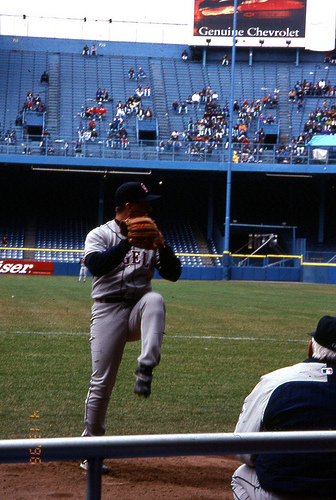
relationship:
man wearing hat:
[84, 179, 166, 437] [115, 179, 154, 202]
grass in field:
[197, 342, 222, 372] [192, 273, 297, 368]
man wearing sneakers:
[81, 179, 181, 470] [138, 364, 154, 397]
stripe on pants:
[83, 384, 90, 408] [80, 298, 164, 431]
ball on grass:
[5, 293, 20, 303] [247, 289, 266, 320]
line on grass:
[186, 331, 220, 341] [223, 350, 244, 379]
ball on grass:
[11, 295, 14, 299] [213, 349, 234, 374]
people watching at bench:
[173, 92, 262, 134] [158, 81, 196, 93]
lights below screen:
[193, 35, 295, 52] [191, 0, 305, 34]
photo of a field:
[14, 71, 291, 446] [182, 274, 265, 361]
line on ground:
[212, 329, 232, 344] [191, 377, 199, 383]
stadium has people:
[24, 100, 271, 215] [84, 114, 233, 117]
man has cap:
[230, 312, 336, 500] [319, 321, 322, 336]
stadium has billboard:
[37, 195, 292, 212] [202, 34, 230, 36]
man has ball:
[230, 312, 336, 500] [139, 226, 146, 234]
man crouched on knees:
[284, 367, 293, 385] [236, 461, 240, 500]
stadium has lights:
[40, 207, 321, 217] [195, 40, 301, 41]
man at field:
[230, 312, 336, 500] [36, 285, 48, 328]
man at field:
[230, 312, 336, 500] [197, 296, 239, 357]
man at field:
[230, 312, 336, 500] [22, 290, 28, 331]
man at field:
[230, 312, 336, 500] [26, 327, 40, 422]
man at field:
[230, 312, 336, 500] [22, 268, 32, 333]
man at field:
[230, 312, 336, 500] [26, 314, 30, 392]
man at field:
[230, 312, 336, 500] [32, 282, 43, 400]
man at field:
[230, 312, 336, 500] [2, 269, 45, 421]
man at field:
[230, 312, 336, 500] [6, 274, 48, 434]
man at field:
[230, 312, 336, 500] [40, 295, 43, 362]